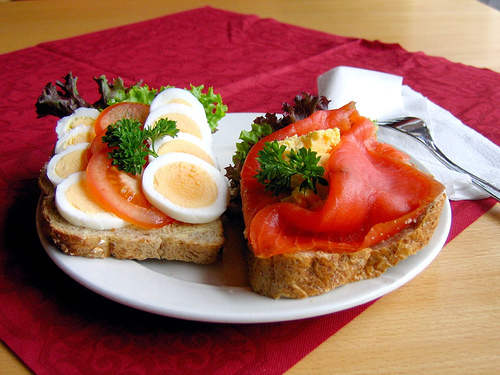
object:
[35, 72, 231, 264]
sandwhich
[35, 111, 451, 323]
plate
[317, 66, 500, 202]
napkin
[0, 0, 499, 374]
table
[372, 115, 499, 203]
fork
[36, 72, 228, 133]
lettuce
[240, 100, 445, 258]
salmon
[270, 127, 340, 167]
eggs